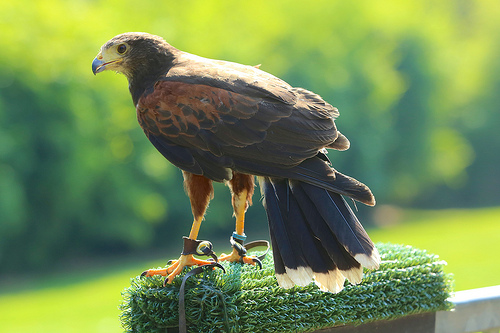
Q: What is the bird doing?
A: Watching.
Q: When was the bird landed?
A: Earlier.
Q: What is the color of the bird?
A: Brown and black.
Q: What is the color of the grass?
A: Green.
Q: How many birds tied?
A: One.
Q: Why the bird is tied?
A: So it won't fly away.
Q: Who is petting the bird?
A: No one.